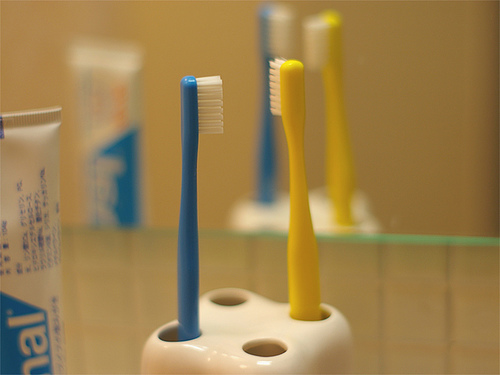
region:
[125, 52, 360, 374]
Two toothbrushes in a holder.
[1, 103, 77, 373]
Part of a tube of toothpaste.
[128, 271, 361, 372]
A container designed for holding toothbrushes.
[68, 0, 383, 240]
A reflection in a mirror.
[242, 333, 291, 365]
A round hole.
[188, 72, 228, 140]
The bristles on a toothbrush.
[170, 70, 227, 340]
A clean blue toothbrush.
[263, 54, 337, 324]
A yellow toothbrush facing towards a mirror.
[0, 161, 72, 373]
Foreign letters on a tube of toothpaste.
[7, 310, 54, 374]
Blue and white letters.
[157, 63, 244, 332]
The toothbrush is blue.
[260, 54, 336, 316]
The toothbrush is yellow.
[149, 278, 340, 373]
The holder is white.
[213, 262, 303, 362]
Holes in the toothbrush holder.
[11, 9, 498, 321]
Mirror on the wall.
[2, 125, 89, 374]
Tube next to the toothpaste.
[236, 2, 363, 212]
Toothbrush reflection on the mirror.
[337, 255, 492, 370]
The wall is white.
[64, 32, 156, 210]
Tube reflection on the mirror.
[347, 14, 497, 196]
Brow wall reflection in the mirror.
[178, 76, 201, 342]
The blue stick of a toothbrush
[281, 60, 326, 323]
The yellow stick of a toothbrush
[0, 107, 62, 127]
The tip of a toothpaste container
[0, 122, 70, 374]
A toothpaste container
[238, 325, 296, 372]
A close toothbrush holder hole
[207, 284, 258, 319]
A far toothbrush holder hole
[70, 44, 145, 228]
A blurry toothpaste container in the distance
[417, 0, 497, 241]
The right-most portion of a mirror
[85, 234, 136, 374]
A small tiled pattern on the wall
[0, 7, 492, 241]
Two Toothbrushes and a Toothpaste Container reflected against a mirror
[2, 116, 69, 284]
toothpaste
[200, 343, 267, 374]
a white toothbrush holder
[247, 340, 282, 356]
holes in the toothbrush holder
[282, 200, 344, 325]
a yellow toothbrush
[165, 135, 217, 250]
blue toothbrush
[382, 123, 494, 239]
a mirror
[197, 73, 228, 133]
bristals on the toothbrush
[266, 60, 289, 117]
white bristals on the yellow toothbrush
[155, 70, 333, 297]
two toothbrushes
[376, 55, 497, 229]
a clear mirror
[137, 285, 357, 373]
The toothbrush holder is white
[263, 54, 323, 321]
The toothbrush is yellow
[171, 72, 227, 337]
The toothbrush is blue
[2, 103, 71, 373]
The toothpaste tube is turned down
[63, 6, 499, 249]
The mirror on the wall of the bathroom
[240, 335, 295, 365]
A hole in the toothbrush holder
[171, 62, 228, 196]
The top of the toothbrush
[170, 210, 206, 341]
The bottom of the toothbrush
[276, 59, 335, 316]
The back of the toothbrush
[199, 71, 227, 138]
The bristles on the toothbrush